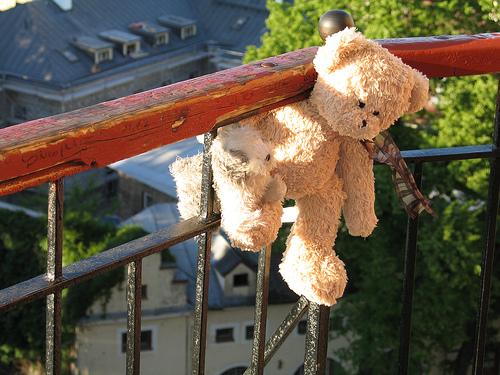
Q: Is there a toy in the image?
A: Yes, there is a toy.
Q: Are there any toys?
A: Yes, there is a toy.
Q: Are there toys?
A: Yes, there is a toy.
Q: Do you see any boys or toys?
A: Yes, there is a toy.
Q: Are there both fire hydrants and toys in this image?
A: No, there is a toy but no fire hydrants.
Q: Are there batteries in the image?
A: No, there are no batteries.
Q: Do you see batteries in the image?
A: No, there are no batteries.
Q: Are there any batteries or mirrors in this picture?
A: No, there are no batteries or mirrors.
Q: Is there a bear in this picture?
A: Yes, there is a bear.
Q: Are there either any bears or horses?
A: Yes, there is a bear.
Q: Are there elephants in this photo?
A: No, there are no elephants.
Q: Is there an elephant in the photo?
A: No, there are no elephants.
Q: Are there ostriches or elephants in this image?
A: No, there are no elephants or ostriches.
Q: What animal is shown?
A: The animal is a bear.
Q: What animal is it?
A: The animal is a bear.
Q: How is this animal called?
A: This is a bear.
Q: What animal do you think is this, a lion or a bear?
A: This is a bear.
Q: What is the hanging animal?
A: The animal is a bear.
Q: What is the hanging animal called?
A: The animal is a bear.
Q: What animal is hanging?
A: The animal is a bear.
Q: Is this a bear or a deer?
A: This is a bear.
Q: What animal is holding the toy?
A: The bear is holding the toy.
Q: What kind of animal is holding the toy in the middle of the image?
A: The animal is a bear.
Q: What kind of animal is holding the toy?
A: The animal is a bear.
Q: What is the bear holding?
A: The bear is holding the toy.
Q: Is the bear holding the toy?
A: Yes, the bear is holding the toy.